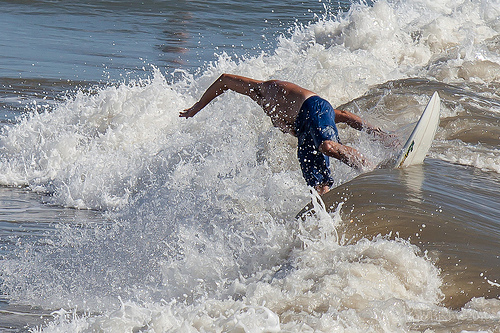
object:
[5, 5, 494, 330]
ocean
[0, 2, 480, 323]
water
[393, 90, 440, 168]
board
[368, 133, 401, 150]
hand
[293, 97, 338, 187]
trunk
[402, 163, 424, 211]
reflection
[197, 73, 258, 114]
arm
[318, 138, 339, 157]
knee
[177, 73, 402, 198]
man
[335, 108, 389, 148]
arm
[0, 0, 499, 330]
wave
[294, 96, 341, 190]
shorts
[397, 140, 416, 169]
lettering